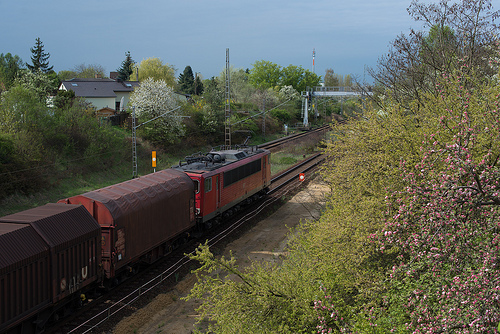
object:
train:
[0, 143, 273, 325]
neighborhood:
[40, 80, 198, 132]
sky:
[0, 0, 498, 89]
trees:
[241, 60, 320, 108]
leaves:
[180, 239, 219, 276]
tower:
[310, 48, 315, 74]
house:
[60, 78, 133, 115]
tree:
[127, 73, 185, 130]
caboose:
[175, 149, 272, 224]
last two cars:
[0, 168, 197, 333]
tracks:
[24, 120, 339, 333]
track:
[246, 120, 339, 150]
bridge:
[301, 89, 374, 97]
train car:
[60, 166, 195, 284]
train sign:
[150, 149, 158, 173]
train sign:
[297, 173, 309, 183]